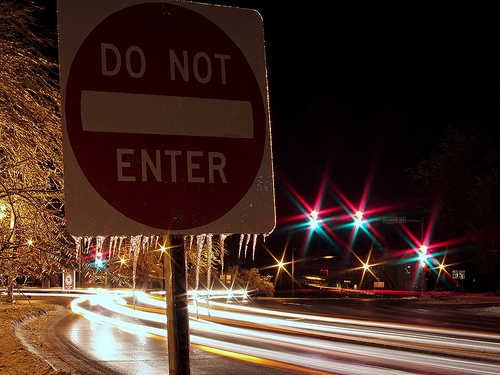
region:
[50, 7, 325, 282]
the sign is square.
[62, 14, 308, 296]
the sign is red and white.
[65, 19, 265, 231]
the text is white.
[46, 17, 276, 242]
the sign says do not enter.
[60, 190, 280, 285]
icicles hanging from the sign.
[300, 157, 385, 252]
the lights are red, blue and white.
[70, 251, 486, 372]
the road is white.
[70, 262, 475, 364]
the road is bright.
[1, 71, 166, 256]
the tree is bare.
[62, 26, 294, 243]
the circle is red.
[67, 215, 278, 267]
Ice cicles hanging from the sign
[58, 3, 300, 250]
White and red sign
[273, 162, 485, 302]
Red and blue blurs of lights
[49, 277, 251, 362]
A blur of car head lights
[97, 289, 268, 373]
Yellow line on the road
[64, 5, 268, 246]
Do Not Enter in a circle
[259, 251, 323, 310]
Regular street lights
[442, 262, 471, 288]
A window in the building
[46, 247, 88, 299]
A white and red sign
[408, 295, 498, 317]
Some snow on the ground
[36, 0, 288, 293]
red do not enter sign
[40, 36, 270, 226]
do not enter sign with the letter d on it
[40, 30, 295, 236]
do not enter sign with the letter o on it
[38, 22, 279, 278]
do not enter sign with the letter n on it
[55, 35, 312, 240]
do not enter sign with the letter t on it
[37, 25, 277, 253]
do not enter sign with the letter e on it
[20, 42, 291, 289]
do not enter sign with the letter r on it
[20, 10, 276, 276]
icicles hanging from a sign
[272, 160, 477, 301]
three red white and blue lights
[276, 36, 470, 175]
dark black skys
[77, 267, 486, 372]
the road is shiny.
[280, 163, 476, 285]
the lights are red, blue and white.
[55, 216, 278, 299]
the icicles are white.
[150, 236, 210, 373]
the pole is metal.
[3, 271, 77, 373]
the grass is brown.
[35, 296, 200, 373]
the curb is grey.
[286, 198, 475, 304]
reflections from the street lamps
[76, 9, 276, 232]
the road sign is red and white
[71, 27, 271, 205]
the sign has a red circle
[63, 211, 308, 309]
icicles hanging from the sign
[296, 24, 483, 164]
the sky is black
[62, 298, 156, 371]
the roads are wet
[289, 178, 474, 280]
the reflection is pink and blue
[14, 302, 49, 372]
frost on the side of road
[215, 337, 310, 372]
yellow line on the road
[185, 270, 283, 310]
the headlights of cars